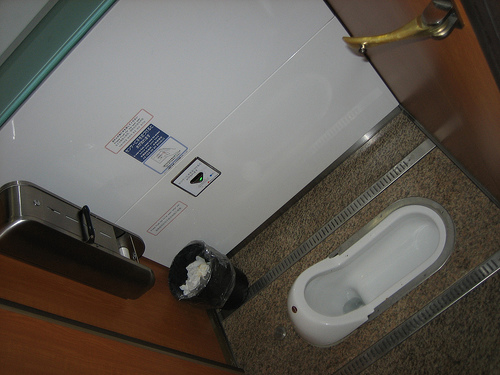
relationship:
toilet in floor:
[276, 201, 457, 350] [183, 122, 498, 373]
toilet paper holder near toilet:
[2, 181, 159, 301] [276, 201, 457, 350]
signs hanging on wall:
[103, 116, 223, 234] [2, 3, 376, 257]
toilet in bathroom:
[276, 201, 457, 350] [2, 3, 499, 375]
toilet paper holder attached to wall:
[2, 181, 159, 301] [0, 212, 243, 374]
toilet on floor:
[276, 201, 457, 350] [183, 122, 498, 373]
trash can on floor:
[157, 239, 250, 311] [183, 122, 498, 373]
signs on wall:
[103, 116, 223, 234] [2, 3, 376, 257]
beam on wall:
[4, 5, 112, 127] [2, 3, 376, 257]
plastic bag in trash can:
[169, 247, 236, 309] [157, 239, 250, 311]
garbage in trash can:
[174, 254, 211, 295] [157, 239, 250, 311]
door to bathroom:
[338, 4, 499, 198] [2, 3, 499, 375]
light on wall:
[198, 174, 205, 185] [2, 3, 376, 257]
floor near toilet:
[183, 122, 498, 373] [276, 201, 457, 350]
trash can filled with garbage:
[157, 239, 250, 311] [174, 254, 211, 295]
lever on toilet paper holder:
[76, 202, 99, 242] [2, 181, 159, 301]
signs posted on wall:
[103, 116, 223, 234] [2, 3, 376, 257]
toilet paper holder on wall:
[2, 181, 159, 301] [0, 212, 243, 374]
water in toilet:
[329, 285, 365, 317] [276, 201, 457, 350]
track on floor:
[327, 266, 499, 375] [183, 122, 498, 373]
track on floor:
[227, 137, 433, 315] [183, 122, 498, 373]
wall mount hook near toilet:
[333, 3, 459, 51] [276, 201, 457, 350]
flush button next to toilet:
[271, 320, 286, 344] [276, 201, 457, 350]